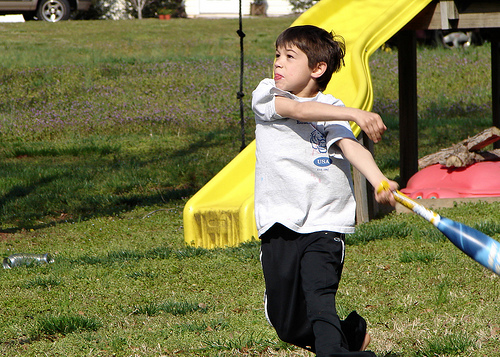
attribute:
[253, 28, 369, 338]
boy — young, playing baseball, little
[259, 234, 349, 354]
pants — black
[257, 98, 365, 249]
shirt — white, grey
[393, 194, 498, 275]
bat — baseball, yellow, blue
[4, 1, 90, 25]
car — parked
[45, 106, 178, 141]
flowers — purple, small, patch, swatch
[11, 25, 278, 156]
lawn — grassy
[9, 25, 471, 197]
landscape — grassy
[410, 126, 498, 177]
logs — wooden, two pieces, wood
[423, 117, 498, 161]
wood — chopped, two pieces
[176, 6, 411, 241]
slide — yellow, plastic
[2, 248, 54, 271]
tube — metal, silver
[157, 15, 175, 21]
pots — orange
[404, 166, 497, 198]
dome — red, plastic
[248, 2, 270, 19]
box — brown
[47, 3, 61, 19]
hubcap — shiny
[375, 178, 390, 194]
tip — yellow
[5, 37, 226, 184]
grass — green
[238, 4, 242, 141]
swing — rope, yellow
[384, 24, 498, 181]
sandbox — covered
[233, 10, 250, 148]
rope — black